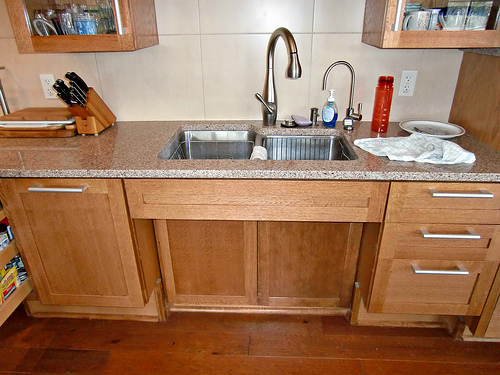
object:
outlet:
[398, 70, 418, 96]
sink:
[158, 129, 358, 160]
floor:
[0, 312, 500, 375]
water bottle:
[371, 75, 395, 133]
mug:
[403, 11, 432, 31]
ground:
[361, 140, 391, 149]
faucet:
[255, 27, 301, 126]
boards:
[0, 107, 78, 138]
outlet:
[38, 73, 58, 99]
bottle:
[371, 75, 395, 133]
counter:
[0, 119, 499, 174]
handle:
[428, 189, 494, 198]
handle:
[420, 229, 482, 239]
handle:
[411, 264, 469, 276]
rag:
[354, 133, 477, 164]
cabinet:
[0, 119, 500, 344]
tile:
[200, 34, 311, 121]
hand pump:
[327, 89, 336, 102]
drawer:
[367, 181, 500, 316]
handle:
[28, 183, 88, 193]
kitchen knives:
[53, 71, 91, 107]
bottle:
[322, 89, 339, 128]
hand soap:
[323, 113, 338, 128]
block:
[68, 87, 117, 137]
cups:
[402, 3, 489, 31]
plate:
[399, 118, 467, 139]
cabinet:
[361, 0, 499, 49]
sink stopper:
[281, 119, 298, 128]